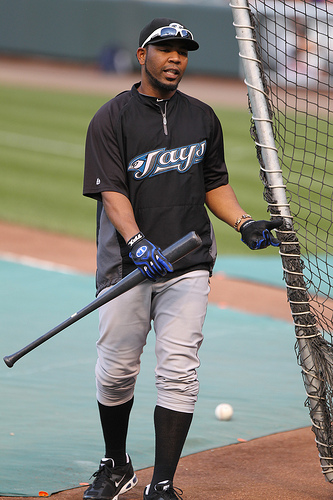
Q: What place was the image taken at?
A: It was taken at the field.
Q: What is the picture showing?
A: It is showing a field.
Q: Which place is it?
A: It is a field.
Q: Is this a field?
A: Yes, it is a field.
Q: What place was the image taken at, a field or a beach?
A: It was taken at a field.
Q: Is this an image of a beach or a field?
A: It is showing a field.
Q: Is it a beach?
A: No, it is a field.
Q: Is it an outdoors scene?
A: Yes, it is outdoors.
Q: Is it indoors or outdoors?
A: It is outdoors.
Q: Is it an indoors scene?
A: No, it is outdoors.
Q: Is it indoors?
A: No, it is outdoors.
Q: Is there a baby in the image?
A: No, there are no babies.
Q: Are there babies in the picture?
A: No, there are no babies.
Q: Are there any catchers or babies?
A: No, there are no babies or catchers.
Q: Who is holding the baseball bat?
A: The man is holding the baseball bat.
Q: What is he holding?
A: The man is holding the baseball bat.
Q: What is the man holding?
A: The man is holding the baseball bat.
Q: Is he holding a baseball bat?
A: Yes, the man is holding a baseball bat.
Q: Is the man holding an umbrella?
A: No, the man is holding a baseball bat.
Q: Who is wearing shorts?
A: The man is wearing shorts.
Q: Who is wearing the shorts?
A: The man is wearing shorts.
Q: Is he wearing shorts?
A: Yes, the man is wearing shorts.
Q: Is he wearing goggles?
A: No, the man is wearing shorts.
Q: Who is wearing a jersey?
A: The man is wearing a jersey.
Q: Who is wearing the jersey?
A: The man is wearing a jersey.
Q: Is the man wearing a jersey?
A: Yes, the man is wearing a jersey.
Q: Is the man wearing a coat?
A: No, the man is wearing a jersey.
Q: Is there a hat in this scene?
A: Yes, there is a hat.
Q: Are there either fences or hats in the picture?
A: Yes, there is a hat.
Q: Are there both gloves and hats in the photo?
A: Yes, there are both a hat and gloves.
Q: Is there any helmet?
A: No, there are no helmets.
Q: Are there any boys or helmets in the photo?
A: No, there are no helmets or boys.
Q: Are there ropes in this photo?
A: No, there are no ropes.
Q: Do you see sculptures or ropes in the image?
A: No, there are no ropes or sculptures.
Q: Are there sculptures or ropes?
A: No, there are no ropes or sculptures.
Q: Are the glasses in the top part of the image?
A: Yes, the glasses are in the top of the image.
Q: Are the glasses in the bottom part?
A: No, the glasses are in the top of the image.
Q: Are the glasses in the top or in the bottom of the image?
A: The glasses are in the top of the image.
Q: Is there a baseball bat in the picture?
A: Yes, there is a baseball bat.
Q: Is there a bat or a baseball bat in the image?
A: Yes, there is a baseball bat.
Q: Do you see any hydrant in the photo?
A: No, there are no fire hydrants.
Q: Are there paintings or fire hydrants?
A: No, there are no fire hydrants or paintings.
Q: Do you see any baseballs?
A: Yes, there is a baseball.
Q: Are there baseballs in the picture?
A: Yes, there is a baseball.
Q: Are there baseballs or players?
A: Yes, there is a baseball.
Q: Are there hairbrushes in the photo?
A: No, there are no hairbrushes.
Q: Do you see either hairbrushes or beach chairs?
A: No, there are no hairbrushes or beach chairs.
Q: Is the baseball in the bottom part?
A: Yes, the baseball is in the bottom of the image.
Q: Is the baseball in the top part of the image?
A: No, the baseball is in the bottom of the image.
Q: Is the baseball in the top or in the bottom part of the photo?
A: The baseball is in the bottom of the image.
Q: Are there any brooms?
A: No, there are no brooms.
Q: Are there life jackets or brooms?
A: No, there are no brooms or life jackets.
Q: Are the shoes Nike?
A: Yes, the shoes are nike.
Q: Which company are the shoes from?
A: The shoes are from nike.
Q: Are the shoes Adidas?
A: No, the shoes are nike.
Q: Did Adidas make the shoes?
A: No, the shoes were made by nike.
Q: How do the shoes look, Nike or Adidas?
A: The shoes are nike.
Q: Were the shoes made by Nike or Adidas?
A: The shoes were made nike.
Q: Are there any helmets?
A: No, there are no helmets.